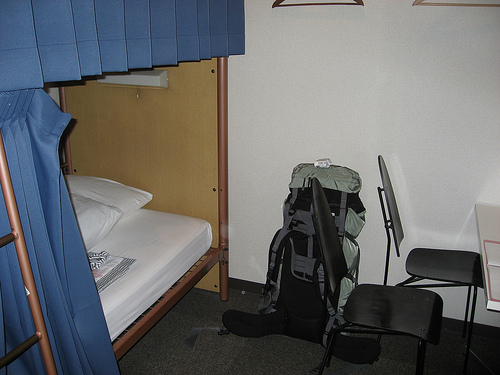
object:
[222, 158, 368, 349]
backpack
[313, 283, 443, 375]
chair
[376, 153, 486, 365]
chair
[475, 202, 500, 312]
desk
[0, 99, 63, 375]
ladder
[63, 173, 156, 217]
pillow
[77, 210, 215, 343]
bed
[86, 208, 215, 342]
mattress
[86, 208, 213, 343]
sheet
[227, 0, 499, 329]
wall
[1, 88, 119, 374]
drape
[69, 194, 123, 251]
pillow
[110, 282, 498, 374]
carpet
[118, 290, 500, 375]
floor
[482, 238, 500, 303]
notebook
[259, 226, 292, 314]
strap